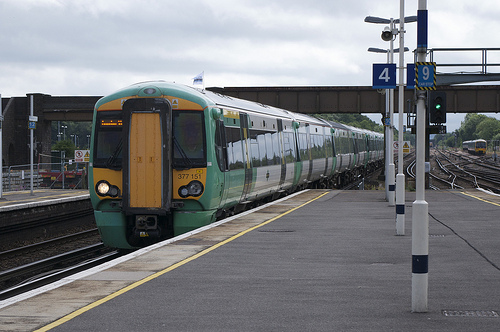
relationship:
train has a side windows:
[86, 81, 385, 250] [215, 125, 385, 174]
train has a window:
[86, 81, 385, 250] [173, 110, 204, 165]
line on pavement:
[28, 190, 333, 331] [0, 188, 500, 331]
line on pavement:
[459, 191, 499, 209] [0, 188, 500, 331]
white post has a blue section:
[411, 0, 428, 313] [410, 254, 430, 274]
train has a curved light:
[86, 81, 385, 250] [138, 85, 159, 97]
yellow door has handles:
[129, 111, 162, 207] [133, 156, 158, 163]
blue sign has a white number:
[372, 63, 396, 88] [377, 68, 392, 83]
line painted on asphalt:
[28, 190, 333, 331] [0, 188, 500, 331]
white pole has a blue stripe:
[411, 0, 428, 313] [410, 254, 430, 274]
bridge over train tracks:
[0, 86, 499, 172] [394, 148, 500, 189]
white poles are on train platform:
[385, 0, 428, 313] [0, 188, 500, 331]